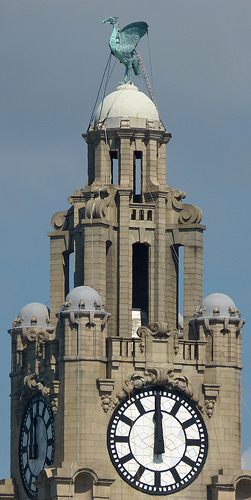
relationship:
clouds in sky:
[21, 9, 61, 55] [181, 38, 230, 101]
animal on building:
[101, 13, 148, 85] [0, 14, 249, 500]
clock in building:
[107, 382, 210, 491] [0, 14, 249, 500]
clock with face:
[113, 382, 216, 491] [125, 412, 192, 477]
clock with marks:
[107, 382, 210, 491] [173, 406, 177, 413]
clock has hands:
[107, 382, 210, 491] [154, 394, 165, 455]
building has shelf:
[0, 14, 249, 500] [203, 382, 220, 418]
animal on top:
[103, 13, 148, 84] [95, 77, 154, 103]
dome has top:
[91, 81, 162, 123] [95, 77, 154, 103]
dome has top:
[91, 81, 162, 123] [93, 77, 163, 134]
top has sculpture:
[93, 77, 163, 134] [101, 16, 151, 83]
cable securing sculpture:
[97, 52, 111, 126] [101, 16, 151, 83]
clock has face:
[107, 382, 210, 491] [106, 389, 210, 495]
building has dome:
[0, 14, 249, 500] [194, 292, 242, 322]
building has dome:
[0, 14, 249, 500] [94, 81, 161, 123]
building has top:
[0, 14, 249, 500] [95, 78, 157, 104]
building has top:
[0, 14, 249, 500] [107, 77, 149, 98]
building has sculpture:
[0, 14, 249, 500] [101, 16, 151, 83]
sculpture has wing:
[101, 16, 151, 83] [120, 20, 149, 53]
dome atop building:
[94, 81, 161, 123] [0, 14, 249, 500]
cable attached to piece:
[97, 52, 111, 126] [107, 43, 118, 58]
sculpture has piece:
[101, 16, 151, 83] [107, 43, 118, 58]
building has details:
[0, 14, 249, 500] [136, 322, 181, 382]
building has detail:
[0, 14, 249, 500] [59, 285, 110, 320]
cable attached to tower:
[133, 154, 205, 316] [0, 15, 250, 499]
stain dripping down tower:
[75, 325, 82, 464] [0, 15, 250, 499]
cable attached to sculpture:
[85, 50, 111, 132] [101, 16, 151, 83]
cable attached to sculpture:
[97, 52, 111, 126] [101, 16, 151, 83]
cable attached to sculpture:
[145, 29, 154, 101] [101, 16, 151, 83]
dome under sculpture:
[91, 81, 162, 123] [101, 16, 151, 83]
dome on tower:
[10, 302, 49, 327] [0, 15, 250, 499]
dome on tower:
[54, 285, 108, 312] [0, 15, 250, 499]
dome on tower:
[194, 292, 241, 323] [0, 15, 250, 499]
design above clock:
[112, 363, 205, 416] [107, 382, 210, 491]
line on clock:
[170, 400, 181, 415] [107, 382, 210, 491]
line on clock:
[182, 416, 197, 428] [107, 382, 210, 491]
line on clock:
[186, 438, 201, 445] [107, 382, 210, 491]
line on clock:
[181, 453, 196, 466] [107, 382, 210, 491]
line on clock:
[169, 465, 180, 482] [107, 382, 210, 491]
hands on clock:
[153, 389, 165, 455] [107, 382, 210, 491]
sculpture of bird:
[101, 16, 151, 83] [92, 10, 152, 76]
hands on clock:
[144, 389, 165, 463] [100, 377, 210, 498]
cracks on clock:
[136, 431, 149, 461] [96, 381, 216, 496]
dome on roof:
[194, 293, 241, 328] [199, 316, 246, 323]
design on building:
[115, 363, 199, 403] [0, 14, 249, 500]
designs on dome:
[52, 305, 120, 332] [54, 281, 108, 316]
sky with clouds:
[12, 11, 243, 285] [5, 11, 244, 294]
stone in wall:
[87, 448, 107, 467] [59, 378, 108, 487]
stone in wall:
[92, 460, 112, 477] [66, 393, 104, 490]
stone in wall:
[214, 439, 233, 451] [206, 415, 241, 492]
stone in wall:
[209, 449, 231, 464] [211, 421, 235, 477]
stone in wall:
[206, 456, 225, 468] [207, 420, 233, 487]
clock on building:
[107, 382, 210, 491] [196, 361, 231, 392]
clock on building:
[107, 382, 210, 491] [197, 336, 230, 361]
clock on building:
[107, 382, 210, 491] [187, 356, 227, 381]